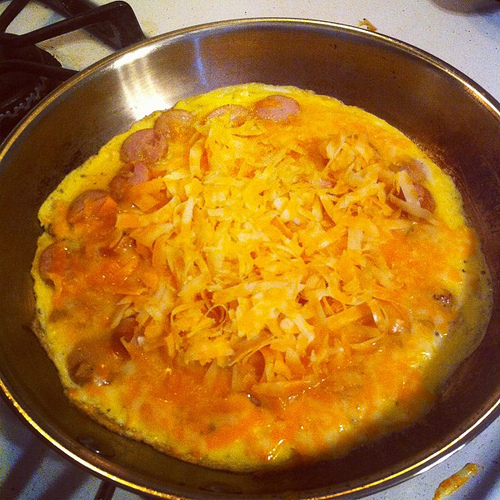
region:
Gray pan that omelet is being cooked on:
[338, 30, 357, 56]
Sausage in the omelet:
[121, 129, 167, 160]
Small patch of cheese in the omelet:
[253, 259, 300, 320]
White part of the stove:
[438, 23, 483, 53]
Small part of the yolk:
[93, 165, 108, 181]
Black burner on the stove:
[7, 35, 35, 74]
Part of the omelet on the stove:
[428, 463, 478, 499]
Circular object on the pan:
[81, 427, 120, 463]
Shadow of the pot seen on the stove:
[16, 450, 48, 498]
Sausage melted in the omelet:
[62, 336, 120, 396]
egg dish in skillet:
[1, 25, 489, 496]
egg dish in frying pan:
[3, 17, 496, 494]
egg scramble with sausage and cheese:
[43, 67, 483, 474]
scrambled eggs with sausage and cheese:
[41, 57, 458, 474]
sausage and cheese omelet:
[39, 77, 475, 444]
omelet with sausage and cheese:
[42, 75, 481, 480]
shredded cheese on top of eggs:
[107, 101, 399, 408]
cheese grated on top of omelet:
[113, 116, 419, 396]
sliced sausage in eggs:
[125, 107, 211, 223]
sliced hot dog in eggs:
[75, 111, 210, 421]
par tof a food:
[295, 364, 297, 370]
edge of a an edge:
[57, 445, 97, 479]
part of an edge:
[435, 425, 461, 450]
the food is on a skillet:
[36, 83, 478, 478]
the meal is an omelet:
[32, 82, 495, 468]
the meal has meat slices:
[119, 130, 168, 166]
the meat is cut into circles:
[71, 191, 116, 233]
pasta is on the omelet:
[122, 145, 380, 373]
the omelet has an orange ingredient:
[118, 335, 265, 450]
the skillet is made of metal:
[6, 20, 498, 491]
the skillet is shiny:
[4, 25, 499, 497]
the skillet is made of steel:
[1, 23, 497, 494]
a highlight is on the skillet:
[102, 35, 167, 117]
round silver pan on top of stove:
[3, 7, 489, 492]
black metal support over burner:
[0, 0, 131, 145]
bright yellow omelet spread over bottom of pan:
[25, 75, 495, 475]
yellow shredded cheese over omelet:
[125, 117, 385, 359]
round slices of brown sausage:
[65, 105, 155, 285]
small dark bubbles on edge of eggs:
[426, 250, 487, 360]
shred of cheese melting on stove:
[425, 456, 480, 493]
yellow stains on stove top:
[15, 5, 155, 70]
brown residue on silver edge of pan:
[6, 390, 171, 495]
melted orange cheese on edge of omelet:
[110, 368, 407, 461]